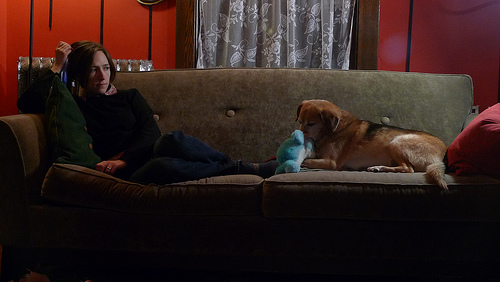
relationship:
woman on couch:
[17, 40, 284, 185] [2, 69, 499, 279]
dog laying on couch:
[259, 100, 451, 190] [2, 69, 499, 279]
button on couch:
[227, 109, 235, 116] [2, 69, 499, 279]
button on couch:
[152, 112, 160, 121] [2, 69, 499, 279]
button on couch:
[382, 116, 390, 123] [2, 69, 499, 279]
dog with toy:
[259, 100, 451, 190] [273, 130, 315, 173]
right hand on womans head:
[52, 41, 71, 75] [69, 43, 116, 94]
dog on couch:
[259, 100, 451, 190] [2, 69, 499, 279]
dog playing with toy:
[259, 100, 451, 190] [273, 130, 315, 173]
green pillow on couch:
[42, 76, 99, 166] [2, 69, 499, 279]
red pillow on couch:
[445, 101, 499, 171] [2, 69, 499, 279]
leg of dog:
[299, 140, 345, 170] [259, 100, 451, 190]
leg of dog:
[365, 145, 415, 174] [259, 100, 451, 190]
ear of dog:
[321, 108, 340, 130] [259, 100, 451, 190]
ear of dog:
[294, 101, 304, 121] [259, 100, 451, 190]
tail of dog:
[426, 158, 449, 192] [259, 100, 451, 190]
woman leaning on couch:
[17, 40, 284, 185] [2, 69, 499, 279]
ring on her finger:
[106, 166, 112, 168] [105, 164, 112, 175]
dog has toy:
[259, 100, 451, 190] [273, 130, 315, 173]